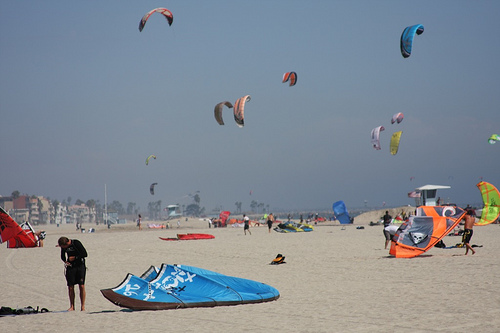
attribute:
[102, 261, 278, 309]
parachute — blue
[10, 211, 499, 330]
sand — tan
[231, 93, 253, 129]
kite — orange, black, white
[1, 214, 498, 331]
ground — sandy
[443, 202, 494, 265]
man — standing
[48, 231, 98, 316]
person — wearing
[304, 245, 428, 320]
beach — sandy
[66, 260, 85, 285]
shorts — black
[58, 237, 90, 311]
man — fiddling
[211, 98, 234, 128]
kite — black, grey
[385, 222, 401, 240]
shirt — white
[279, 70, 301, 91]
kite — white, black, red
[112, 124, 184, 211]
kite — distant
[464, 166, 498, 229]
parachute — yellow and orange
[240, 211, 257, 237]
outfit — white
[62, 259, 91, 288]
shorts — black